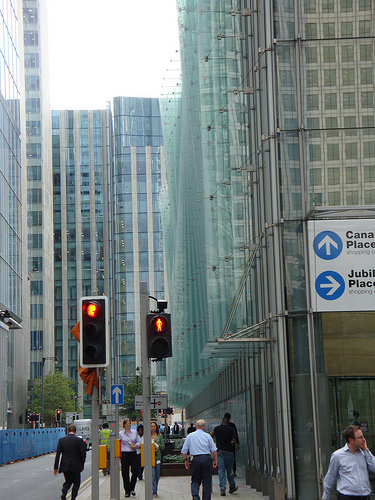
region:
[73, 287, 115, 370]
traffic light on pole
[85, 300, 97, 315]
red light is lit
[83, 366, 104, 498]
pole is color gray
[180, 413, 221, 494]
man with blue shirt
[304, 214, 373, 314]
a street sign with arrows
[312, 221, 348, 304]
the arrows are white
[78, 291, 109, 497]
red traffic light on a silver pole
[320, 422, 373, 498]
man with his hand to his face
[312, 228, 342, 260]
blue circle with white arrow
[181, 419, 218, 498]
man wearing a light blue shirt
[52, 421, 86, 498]
man wearing a black suit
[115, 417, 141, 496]
woman wearing black pants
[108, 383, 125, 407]
rectangular blue sign with white arrow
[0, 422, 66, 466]
blue construction barrier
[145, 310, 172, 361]
black light fixture with red light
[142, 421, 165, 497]
woman wearing green shirt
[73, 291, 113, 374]
traffic light is red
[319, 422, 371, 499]
man wearing light blue shirt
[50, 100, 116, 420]
tall building behind street light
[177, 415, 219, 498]
balding man in blue shirt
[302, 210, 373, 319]
white and blue sign with arrows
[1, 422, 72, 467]
blue traffic barrier next to road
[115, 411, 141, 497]
man in lavender shirt between poles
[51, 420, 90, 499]
man in black business suit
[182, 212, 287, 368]
metal framed overhang on building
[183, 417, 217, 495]
man wearing light blue shirt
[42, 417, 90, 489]
man wearing dark suit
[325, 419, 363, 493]
man talking on cellphone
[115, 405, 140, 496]
woman wearing lavender shirt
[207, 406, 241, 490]
man wearing black t-shirt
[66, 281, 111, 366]
traffic light on red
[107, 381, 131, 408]
blue arrow street sign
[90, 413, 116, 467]
man wearing yellow vest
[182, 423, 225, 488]
man wearing blue pants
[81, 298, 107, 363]
stop light is red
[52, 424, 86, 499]
man wearing a dark suit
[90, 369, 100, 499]
stop light on a pole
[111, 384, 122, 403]
blue sign with an arrow on it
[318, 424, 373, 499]
man talking on his phone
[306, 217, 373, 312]
sign is white, blue and black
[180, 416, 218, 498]
man wearing a blue shirt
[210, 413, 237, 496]
man wearing a black shirt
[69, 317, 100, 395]
red fabric behind stop light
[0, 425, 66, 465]
wall divider is blue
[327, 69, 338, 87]
WINDOWS ON THE BUILDING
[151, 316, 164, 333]
RED NO WALKING SIGNAL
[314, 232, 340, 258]
ARROW POINTING STRAIGHT UP